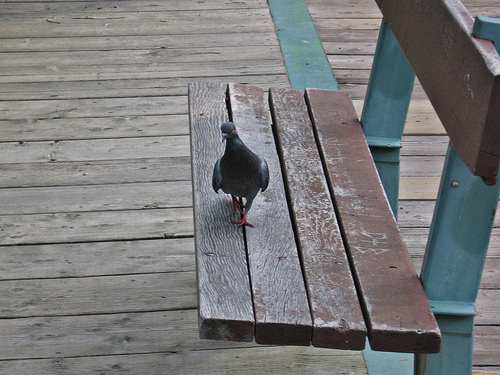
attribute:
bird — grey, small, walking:
[209, 116, 272, 233]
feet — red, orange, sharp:
[229, 195, 256, 232]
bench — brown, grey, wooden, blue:
[178, 3, 496, 375]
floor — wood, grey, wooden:
[5, 3, 199, 374]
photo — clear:
[2, 2, 500, 375]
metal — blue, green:
[433, 199, 499, 374]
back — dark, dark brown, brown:
[378, 1, 499, 187]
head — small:
[215, 115, 246, 148]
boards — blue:
[366, 48, 490, 374]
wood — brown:
[183, 73, 442, 365]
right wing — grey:
[258, 155, 272, 195]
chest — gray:
[222, 146, 258, 185]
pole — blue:
[421, 144, 487, 374]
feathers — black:
[207, 116, 276, 213]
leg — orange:
[231, 211, 256, 230]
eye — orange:
[231, 127, 239, 131]